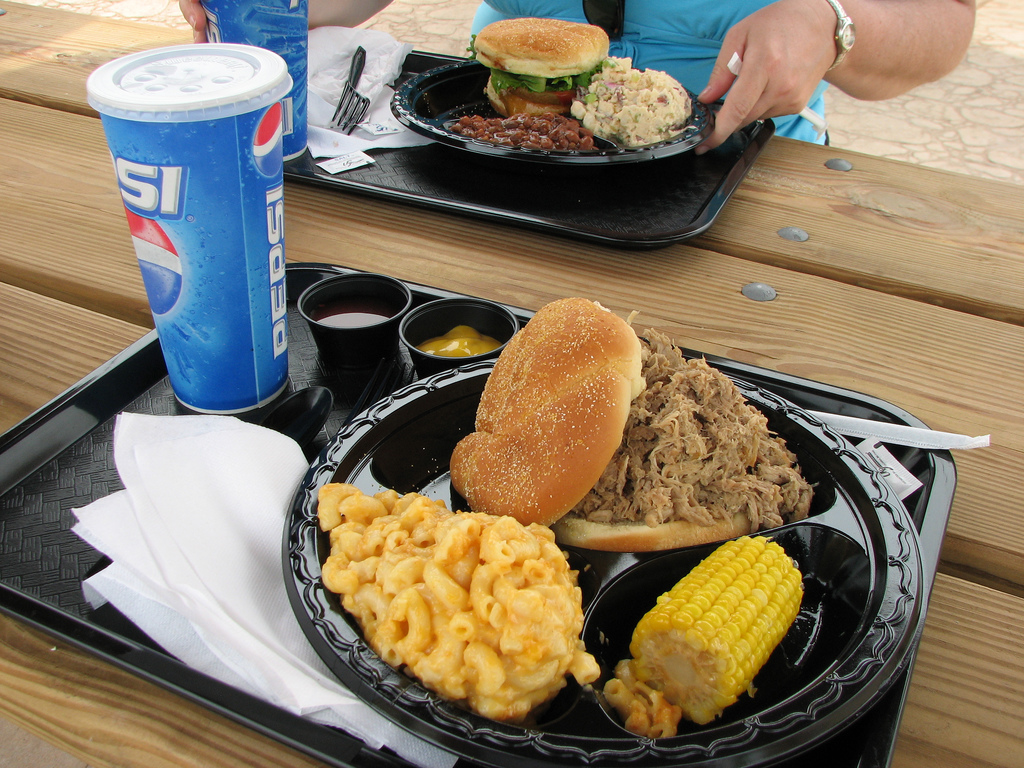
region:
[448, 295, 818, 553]
Pork sandwich sitting on black plate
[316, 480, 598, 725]
Macaroni and cheese sitting on plate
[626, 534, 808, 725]
Piece of corn on the cob on plate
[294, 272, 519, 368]
Sauces in containers sitting on tray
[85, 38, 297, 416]
Large soft drink sitting on tray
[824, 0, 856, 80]
Watch on person's wrist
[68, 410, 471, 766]
Napkins sitting next to plate of food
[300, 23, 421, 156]
Fork on top of napkin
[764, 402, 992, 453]
Straw in wrapper sitting on tray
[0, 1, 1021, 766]
Two trays of food on a picnic table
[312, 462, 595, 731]
Macaroni and cheese on the plate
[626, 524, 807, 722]
Corn on the cob on the plate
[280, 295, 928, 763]
Food on a black plate on a tray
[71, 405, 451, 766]
Napkins on the tray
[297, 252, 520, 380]
Containers of ketchup and mustard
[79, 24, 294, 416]
Soft drink cup on the tray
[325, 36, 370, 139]
A fork on the napkin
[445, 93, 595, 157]
Baked beans on the tray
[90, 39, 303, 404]
Blue Pepsi cup with white lid.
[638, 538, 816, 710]
Yellow corn on the cob.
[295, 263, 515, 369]
Two small black bowls with sauces.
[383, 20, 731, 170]
Black plastic plate with food.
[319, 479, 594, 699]
Serving of mac and cheese.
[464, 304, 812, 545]
BBQ on a bun.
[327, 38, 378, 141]
A black plastic fork.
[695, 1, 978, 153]
Arm with a gold watch.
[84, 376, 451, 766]
White napkins and a black spoon.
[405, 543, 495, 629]
the macarroni's are chessy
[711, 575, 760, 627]
the corn on the cob is yellow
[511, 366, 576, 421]
the bun is golden brown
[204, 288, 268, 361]
the cup is blue in color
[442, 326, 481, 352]
the mustard is yellow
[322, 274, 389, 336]
the sauce is in the container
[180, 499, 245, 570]
the napkins are white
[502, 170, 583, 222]
the tray is black in color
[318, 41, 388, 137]
the fork is laying on the napkin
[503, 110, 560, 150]
the baked beans are brown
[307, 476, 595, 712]
macaroni and cheese on the plate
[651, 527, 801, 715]
piece of corn on the cob on the plate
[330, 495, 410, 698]
food on a plate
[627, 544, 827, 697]
food on a plate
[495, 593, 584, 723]
food on a plate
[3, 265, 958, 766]
food on a plastic plate and tray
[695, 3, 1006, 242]
person in a blue shirt and a wristwatch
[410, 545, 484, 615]
A piece of food.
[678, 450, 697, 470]
A piece of food.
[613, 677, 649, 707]
A piece of food.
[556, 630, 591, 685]
A piece of food.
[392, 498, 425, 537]
A piece of food.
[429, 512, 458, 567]
A piece of food.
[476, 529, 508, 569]
A piece of food.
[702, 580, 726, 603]
A piece of food.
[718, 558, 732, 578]
A piece of food.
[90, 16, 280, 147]
the lid of a cup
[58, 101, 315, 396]
a cup that is blue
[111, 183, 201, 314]
the logo on a cup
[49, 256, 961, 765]
a tray that is black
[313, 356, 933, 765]
a plate that is black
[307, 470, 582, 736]
some macaroni and cheese that is orange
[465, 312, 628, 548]
a piece of bread that is brown